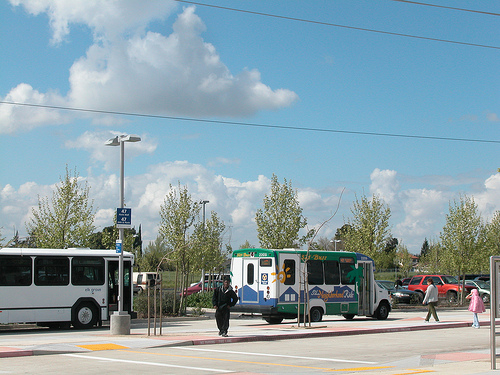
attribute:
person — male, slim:
[418, 275, 448, 317]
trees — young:
[18, 164, 488, 310]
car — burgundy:
[178, 280, 214, 294]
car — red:
[386, 254, 497, 334]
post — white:
[118, 140, 125, 312]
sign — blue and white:
[114, 207, 131, 224]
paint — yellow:
[78, 335, 123, 352]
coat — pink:
[469, 287, 486, 314]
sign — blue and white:
[113, 204, 132, 231]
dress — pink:
[465, 276, 489, 335]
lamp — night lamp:
[102, 131, 142, 335]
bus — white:
[0, 248, 140, 330]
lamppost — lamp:
[106, 128, 147, 335]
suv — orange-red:
[407, 271, 467, 303]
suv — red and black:
[406, 272, 480, 311]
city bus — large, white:
[3, 237, 142, 332]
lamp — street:
[82, 97, 150, 351]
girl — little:
[463, 283, 487, 331]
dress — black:
[213, 284, 238, 329]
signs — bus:
[114, 202, 134, 231]